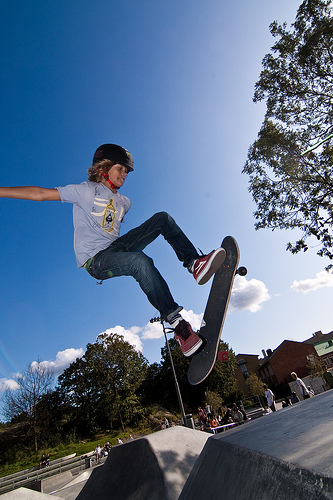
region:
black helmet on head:
[90, 143, 136, 172]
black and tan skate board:
[186, 236, 238, 384]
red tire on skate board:
[218, 350, 228, 363]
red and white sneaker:
[173, 322, 203, 358]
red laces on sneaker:
[163, 320, 192, 342]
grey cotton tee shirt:
[56, 179, 132, 269]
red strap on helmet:
[99, 168, 118, 192]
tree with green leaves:
[59, 332, 147, 431]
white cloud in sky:
[229, 274, 268, 313]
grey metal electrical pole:
[148, 314, 194, 430]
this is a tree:
[237, 0, 331, 279]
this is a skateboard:
[182, 233, 247, 390]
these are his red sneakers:
[167, 244, 227, 359]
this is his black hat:
[88, 143, 136, 173]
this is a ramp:
[176, 378, 329, 497]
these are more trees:
[1, 328, 238, 476]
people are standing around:
[191, 372, 318, 440]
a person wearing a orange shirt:
[208, 415, 219, 430]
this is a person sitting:
[37, 451, 49, 471]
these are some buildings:
[224, 328, 331, 404]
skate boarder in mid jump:
[3, 138, 253, 392]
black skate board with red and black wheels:
[175, 234, 252, 390]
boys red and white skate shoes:
[166, 248, 227, 361]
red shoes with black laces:
[158, 246, 234, 361]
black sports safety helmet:
[90, 138, 136, 178]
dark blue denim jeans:
[85, 207, 209, 322]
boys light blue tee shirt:
[52, 172, 133, 271]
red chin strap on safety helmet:
[96, 166, 123, 195]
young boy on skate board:
[4, 141, 250, 392]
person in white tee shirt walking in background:
[287, 368, 313, 398]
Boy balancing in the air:
[0, 141, 226, 360]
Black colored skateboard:
[186, 233, 247, 389]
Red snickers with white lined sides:
[172, 245, 227, 358]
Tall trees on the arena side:
[65, 328, 241, 439]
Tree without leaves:
[0, 357, 55, 459]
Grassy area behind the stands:
[2, 426, 128, 480]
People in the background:
[37, 371, 329, 468]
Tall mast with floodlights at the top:
[147, 309, 195, 425]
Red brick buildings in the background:
[229, 329, 332, 397]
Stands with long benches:
[0, 408, 238, 494]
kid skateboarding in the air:
[34, 137, 280, 392]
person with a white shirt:
[260, 378, 276, 414]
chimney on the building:
[265, 344, 272, 353]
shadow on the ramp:
[158, 446, 200, 476]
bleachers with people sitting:
[13, 469, 40, 480]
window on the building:
[240, 358, 247, 370]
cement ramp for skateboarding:
[234, 428, 270, 453]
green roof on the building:
[310, 335, 332, 357]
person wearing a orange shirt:
[209, 409, 217, 430]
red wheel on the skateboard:
[218, 344, 229, 363]